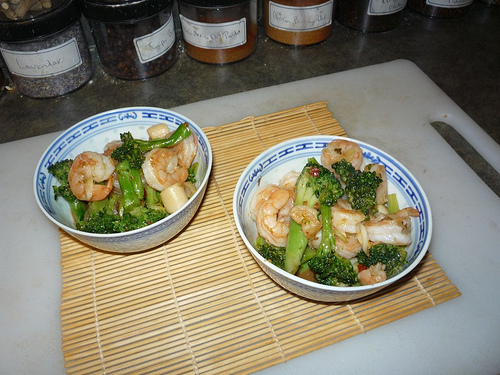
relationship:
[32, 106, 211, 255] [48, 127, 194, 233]
bowl of food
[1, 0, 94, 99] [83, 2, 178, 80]
containers have spices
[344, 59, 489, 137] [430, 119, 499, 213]
cutting board has a handle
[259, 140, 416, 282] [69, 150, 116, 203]
food in bowl shrimp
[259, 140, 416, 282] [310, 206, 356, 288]
food in bowl broccoli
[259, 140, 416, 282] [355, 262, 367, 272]
food in bowl has a red pepper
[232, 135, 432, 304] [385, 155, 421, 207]
ceramic bowl has blue on the rim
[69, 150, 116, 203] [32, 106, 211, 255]
shrimp in bowl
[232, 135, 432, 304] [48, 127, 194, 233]
two bowls of food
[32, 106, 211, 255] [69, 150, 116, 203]
bowl of shrimp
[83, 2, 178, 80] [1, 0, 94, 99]
spices in jar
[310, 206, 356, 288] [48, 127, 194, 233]
broccoli in food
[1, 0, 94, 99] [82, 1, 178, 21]
spice jars have a top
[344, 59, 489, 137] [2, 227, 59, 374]
cutting board made of plastic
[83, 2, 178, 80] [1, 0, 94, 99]
spices are in jars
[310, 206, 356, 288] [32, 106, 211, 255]
broccoli in each bowl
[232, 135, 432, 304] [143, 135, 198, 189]
bowl has sea food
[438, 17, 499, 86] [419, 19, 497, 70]
dark granite on counter top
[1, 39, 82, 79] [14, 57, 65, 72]
label says lavender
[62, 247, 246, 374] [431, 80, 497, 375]
placemat on cutting board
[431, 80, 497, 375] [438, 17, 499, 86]
cutting board on counter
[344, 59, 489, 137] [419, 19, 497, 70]
cutting board on counter top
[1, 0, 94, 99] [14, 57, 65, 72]
spice jar has lavender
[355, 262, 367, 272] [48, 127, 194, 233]
hot peppers in food